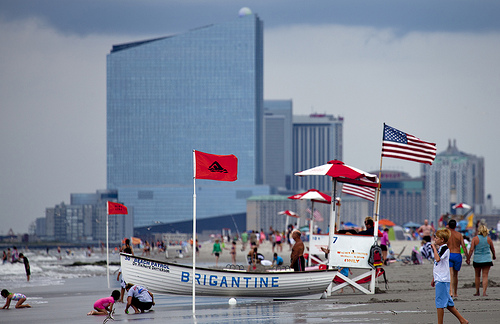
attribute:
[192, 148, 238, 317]
flag — red, black, white, blue, blowing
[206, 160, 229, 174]
logo — black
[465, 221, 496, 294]
woman — blonde, walking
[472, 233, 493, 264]
tank — blue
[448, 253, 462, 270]
shorts — blue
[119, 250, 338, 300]
boat — blue, white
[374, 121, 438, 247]
flag — american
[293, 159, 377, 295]
umbrella — red, white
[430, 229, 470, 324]
boy — blonde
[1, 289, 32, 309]
girl — playing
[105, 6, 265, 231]
building — high, large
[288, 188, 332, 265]
umbrella — white, red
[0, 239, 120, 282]
people — playng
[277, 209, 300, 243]
umbrella — red, white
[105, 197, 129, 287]
flag — red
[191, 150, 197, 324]
pole — white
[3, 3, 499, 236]
sky — gray, cloudy